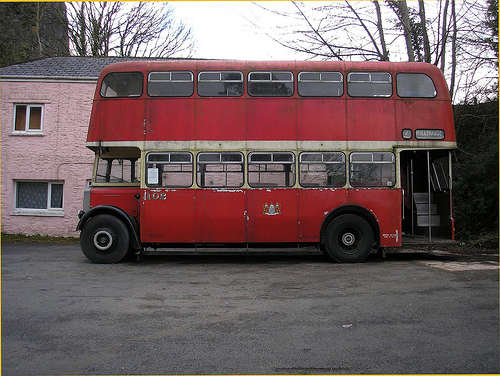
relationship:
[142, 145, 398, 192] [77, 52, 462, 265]
windows on bus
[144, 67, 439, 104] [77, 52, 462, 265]
windows on bus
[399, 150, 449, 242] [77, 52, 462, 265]
door to bus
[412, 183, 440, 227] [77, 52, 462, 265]
stair on bus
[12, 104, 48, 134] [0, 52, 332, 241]
window on building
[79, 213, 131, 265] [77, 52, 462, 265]
wheel on bus